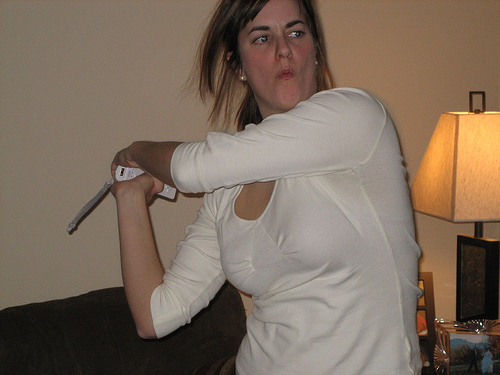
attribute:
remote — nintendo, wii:
[64, 160, 175, 231]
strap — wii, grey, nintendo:
[65, 181, 110, 236]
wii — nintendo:
[111, 159, 177, 201]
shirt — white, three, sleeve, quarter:
[148, 83, 418, 369]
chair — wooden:
[419, 268, 435, 368]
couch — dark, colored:
[10, 285, 248, 365]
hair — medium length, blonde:
[175, 0, 338, 130]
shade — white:
[409, 107, 499, 223]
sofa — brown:
[0, 279, 252, 371]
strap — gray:
[63, 182, 114, 234]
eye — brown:
[286, 25, 307, 41]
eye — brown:
[251, 33, 271, 45]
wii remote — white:
[113, 161, 181, 199]